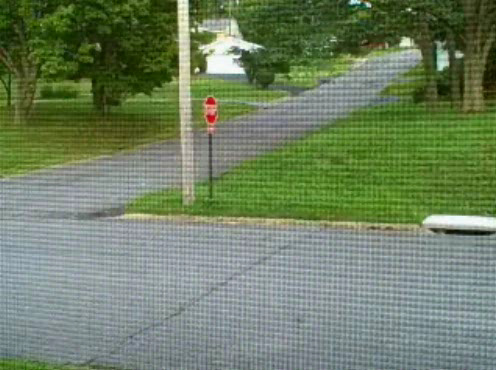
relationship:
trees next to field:
[17, 1, 481, 128] [15, 8, 481, 215]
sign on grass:
[201, 94, 222, 203] [126, 56, 494, 222]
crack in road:
[146, 280, 268, 328] [0, 211, 487, 369]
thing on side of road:
[416, 206, 493, 238] [0, 211, 487, 369]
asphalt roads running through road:
[1, 240, 484, 367] [0, 211, 487, 369]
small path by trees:
[8, 90, 271, 108] [255, 24, 495, 113]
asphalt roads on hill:
[1, 240, 484, 367] [280, 34, 444, 98]